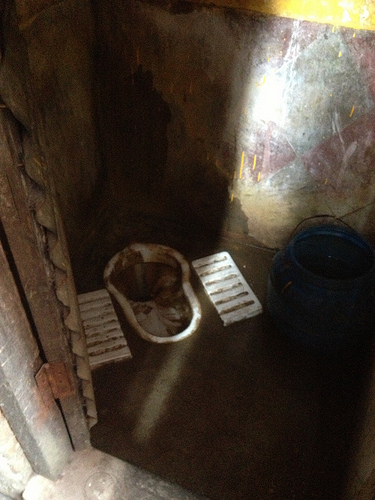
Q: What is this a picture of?
A: An outdoor latrine.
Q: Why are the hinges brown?
A: Because they are rusted.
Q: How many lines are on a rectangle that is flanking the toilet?
A: Six.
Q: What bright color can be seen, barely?
A: Yellow.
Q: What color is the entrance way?
A: Gray.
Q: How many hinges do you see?
A: One.